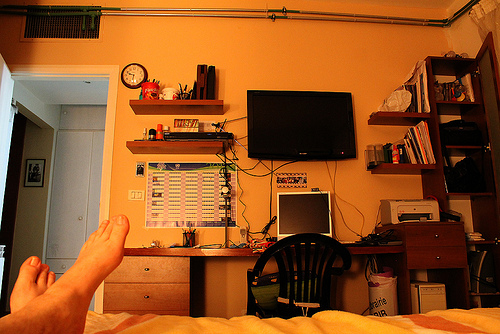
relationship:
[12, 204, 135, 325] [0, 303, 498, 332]
feet on bed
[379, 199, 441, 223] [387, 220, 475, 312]
printer on desk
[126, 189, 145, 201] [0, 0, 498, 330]
light switch on wall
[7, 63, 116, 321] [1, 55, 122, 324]
trim on doorway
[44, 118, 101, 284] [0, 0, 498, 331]
doors outside of room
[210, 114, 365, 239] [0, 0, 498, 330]
electronic wires on wall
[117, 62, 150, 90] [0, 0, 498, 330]
clock on wall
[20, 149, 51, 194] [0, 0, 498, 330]
picture hanging on wall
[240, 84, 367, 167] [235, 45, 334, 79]
tv on wall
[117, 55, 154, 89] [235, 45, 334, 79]
clock on wall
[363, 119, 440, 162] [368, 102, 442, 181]
books on shelf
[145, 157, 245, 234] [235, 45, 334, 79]
poster on wall